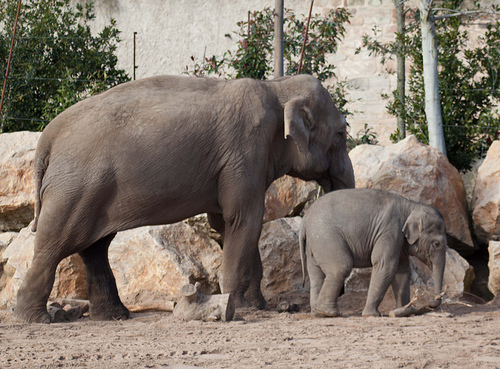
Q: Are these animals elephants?
A: Yes, all the animals are elephants.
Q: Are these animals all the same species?
A: Yes, all the animals are elephants.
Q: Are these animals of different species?
A: No, all the animals are elephants.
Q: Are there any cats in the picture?
A: No, there are no cats.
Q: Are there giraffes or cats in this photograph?
A: No, there are no cats or giraffes.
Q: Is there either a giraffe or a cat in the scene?
A: No, there are no cats or giraffes.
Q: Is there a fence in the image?
A: Yes, there is a fence.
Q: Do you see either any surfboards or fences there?
A: Yes, there is a fence.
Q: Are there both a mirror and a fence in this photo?
A: No, there is a fence but no mirrors.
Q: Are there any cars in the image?
A: No, there are no cars.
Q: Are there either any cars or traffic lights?
A: No, there are no cars or traffic lights.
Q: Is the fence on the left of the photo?
A: Yes, the fence is on the left of the image.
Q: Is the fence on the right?
A: No, the fence is on the left of the image.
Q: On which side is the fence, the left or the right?
A: The fence is on the left of the image.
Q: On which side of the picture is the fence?
A: The fence is on the left of the image.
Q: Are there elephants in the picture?
A: Yes, there are elephants.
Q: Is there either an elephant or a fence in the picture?
A: Yes, there are elephants.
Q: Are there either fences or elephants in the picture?
A: Yes, there are elephants.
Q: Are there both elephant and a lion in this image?
A: No, there are elephants but no lions.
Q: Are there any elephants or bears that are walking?
A: Yes, the elephants are walking.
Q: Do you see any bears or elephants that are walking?
A: Yes, the elephants are walking.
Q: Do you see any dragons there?
A: No, there are no dragons.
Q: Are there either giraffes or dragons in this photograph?
A: No, there are no dragons or giraffes.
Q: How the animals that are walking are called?
A: The animals are elephants.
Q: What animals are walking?
A: The animals are elephants.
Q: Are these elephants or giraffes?
A: These are elephants.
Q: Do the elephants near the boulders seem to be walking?
A: Yes, the elephants are walking.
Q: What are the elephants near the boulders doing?
A: The elephants are walking.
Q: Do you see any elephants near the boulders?
A: Yes, there are elephants near the boulders.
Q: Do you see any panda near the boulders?
A: No, there are elephants near the boulders.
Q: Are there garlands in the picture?
A: No, there are no garlands.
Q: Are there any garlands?
A: No, there are no garlands.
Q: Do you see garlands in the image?
A: No, there are no garlands.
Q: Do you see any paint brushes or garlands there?
A: No, there are no garlands or paint brushes.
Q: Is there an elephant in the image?
A: Yes, there is an elephant.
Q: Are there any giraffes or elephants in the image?
A: Yes, there is an elephant.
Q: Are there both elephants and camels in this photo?
A: No, there is an elephant but no camels.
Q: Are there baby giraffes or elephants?
A: Yes, there is a baby elephant.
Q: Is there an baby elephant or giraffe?
A: Yes, there is a baby elephant.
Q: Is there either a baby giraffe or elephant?
A: Yes, there is a baby elephant.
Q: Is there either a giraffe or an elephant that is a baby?
A: Yes, the elephant is a baby.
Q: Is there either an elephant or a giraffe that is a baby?
A: Yes, the elephant is a baby.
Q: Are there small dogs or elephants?
A: Yes, there is a small elephant.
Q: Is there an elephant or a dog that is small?
A: Yes, the elephant is small.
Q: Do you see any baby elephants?
A: Yes, there is a baby elephant.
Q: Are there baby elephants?
A: Yes, there is a baby elephant.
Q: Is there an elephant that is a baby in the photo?
A: Yes, there is a baby elephant.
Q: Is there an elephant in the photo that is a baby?
A: Yes, there is an elephant that is a baby.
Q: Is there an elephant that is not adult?
A: Yes, there is an baby elephant.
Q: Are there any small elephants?
A: Yes, there is a small elephant.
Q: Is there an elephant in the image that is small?
A: Yes, there is an elephant that is small.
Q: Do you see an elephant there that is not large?
A: Yes, there is a small elephant.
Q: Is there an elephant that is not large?
A: Yes, there is a small elephant.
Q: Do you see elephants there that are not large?
A: Yes, there is a small elephant.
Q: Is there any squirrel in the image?
A: No, there are no squirrels.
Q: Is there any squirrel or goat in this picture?
A: No, there are no squirrels or goats.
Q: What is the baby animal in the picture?
A: The animal is an elephant.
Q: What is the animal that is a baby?
A: The animal is an elephant.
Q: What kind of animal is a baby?
A: The animal is an elephant.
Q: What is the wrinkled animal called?
A: The animal is an elephant.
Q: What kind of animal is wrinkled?
A: The animal is an elephant.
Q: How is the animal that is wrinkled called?
A: The animal is an elephant.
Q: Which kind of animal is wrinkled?
A: The animal is an elephant.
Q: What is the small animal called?
A: The animal is an elephant.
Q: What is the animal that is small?
A: The animal is an elephant.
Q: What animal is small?
A: The animal is an elephant.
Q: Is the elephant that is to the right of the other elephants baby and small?
A: Yes, the elephant is a baby and small.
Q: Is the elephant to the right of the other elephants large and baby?
A: No, the elephant is a baby but small.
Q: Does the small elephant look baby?
A: Yes, the elephant is a baby.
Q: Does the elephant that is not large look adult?
A: No, the elephant is a baby.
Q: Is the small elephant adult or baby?
A: The elephant is a baby.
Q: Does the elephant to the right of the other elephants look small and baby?
A: Yes, the elephant is small and baby.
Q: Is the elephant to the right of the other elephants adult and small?
A: No, the elephant is small but baby.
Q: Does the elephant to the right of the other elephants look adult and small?
A: No, the elephant is small but baby.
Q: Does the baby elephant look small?
A: Yes, the elephant is small.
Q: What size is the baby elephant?
A: The elephant is small.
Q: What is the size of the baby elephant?
A: The elephant is small.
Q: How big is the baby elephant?
A: The elephant is small.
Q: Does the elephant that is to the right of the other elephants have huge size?
A: No, the elephant is small.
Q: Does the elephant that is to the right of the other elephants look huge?
A: No, the elephant is small.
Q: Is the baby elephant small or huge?
A: The elephant is small.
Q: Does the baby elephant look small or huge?
A: The elephant is small.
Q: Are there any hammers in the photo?
A: No, there are no hammers.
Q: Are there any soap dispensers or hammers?
A: No, there are no hammers or soap dispensers.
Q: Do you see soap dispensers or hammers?
A: No, there are no hammers or soap dispensers.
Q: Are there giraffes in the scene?
A: No, there are no giraffes.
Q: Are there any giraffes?
A: No, there are no giraffes.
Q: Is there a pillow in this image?
A: No, there are no pillows.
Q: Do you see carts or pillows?
A: No, there are no pillows or carts.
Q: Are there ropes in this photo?
A: No, there are no ropes.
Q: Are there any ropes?
A: No, there are no ropes.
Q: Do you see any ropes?
A: No, there are no ropes.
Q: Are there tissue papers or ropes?
A: No, there are no ropes or tissue papers.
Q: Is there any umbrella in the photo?
A: No, there are no umbrellas.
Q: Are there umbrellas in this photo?
A: No, there are no umbrellas.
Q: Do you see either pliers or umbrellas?
A: No, there are no umbrellas or pliers.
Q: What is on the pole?
A: The wires are on the pole.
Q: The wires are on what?
A: The wires are on the pole.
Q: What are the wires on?
A: The wires are on the pole.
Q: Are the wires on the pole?
A: Yes, the wires are on the pole.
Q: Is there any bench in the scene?
A: No, there are no benches.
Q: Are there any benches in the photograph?
A: No, there are no benches.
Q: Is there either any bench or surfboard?
A: No, there are no benches or surfboards.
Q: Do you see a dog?
A: No, there are no dogs.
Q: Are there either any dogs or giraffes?
A: No, there are no dogs or giraffes.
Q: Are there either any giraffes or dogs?
A: No, there are no dogs or giraffes.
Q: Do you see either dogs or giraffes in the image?
A: No, there are no dogs or giraffes.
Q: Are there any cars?
A: No, there are no cars.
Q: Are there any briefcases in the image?
A: No, there are no briefcases.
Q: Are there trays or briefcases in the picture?
A: No, there are no briefcases or trays.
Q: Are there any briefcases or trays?
A: No, there are no briefcases or trays.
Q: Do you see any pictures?
A: No, there are no pictures.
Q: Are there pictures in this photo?
A: No, there are no pictures.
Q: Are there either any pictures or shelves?
A: No, there are no pictures or shelves.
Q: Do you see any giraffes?
A: No, there are no giraffes.